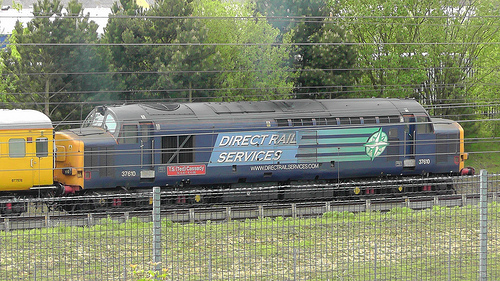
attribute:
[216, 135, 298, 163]
writing — white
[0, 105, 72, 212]
car — yellow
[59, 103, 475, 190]
engine — gray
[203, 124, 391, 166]
logo — blue, white, green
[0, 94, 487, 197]
train — blue and yellow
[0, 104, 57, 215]
train car — yellow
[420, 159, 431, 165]
numbers — white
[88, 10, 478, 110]
lines — electrical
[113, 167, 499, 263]
mesh — wire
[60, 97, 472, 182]
train — blue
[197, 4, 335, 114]
tree — green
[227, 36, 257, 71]
leaves — green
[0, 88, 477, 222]
train — cargo